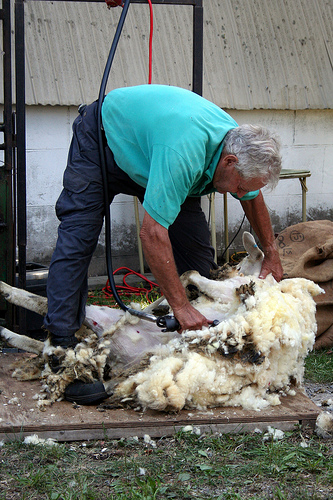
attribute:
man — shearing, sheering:
[44, 82, 285, 371]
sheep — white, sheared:
[0, 230, 326, 410]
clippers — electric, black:
[155, 316, 219, 332]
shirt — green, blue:
[104, 84, 260, 229]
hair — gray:
[226, 124, 282, 190]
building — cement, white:
[1, 1, 332, 277]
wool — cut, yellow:
[122, 273, 324, 412]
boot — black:
[49, 336, 109, 405]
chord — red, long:
[93, 0, 164, 324]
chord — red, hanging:
[101, 1, 159, 302]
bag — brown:
[257, 218, 332, 352]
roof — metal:
[0, 0, 332, 110]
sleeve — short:
[144, 146, 204, 230]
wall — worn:
[0, 106, 332, 286]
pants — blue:
[45, 94, 215, 337]